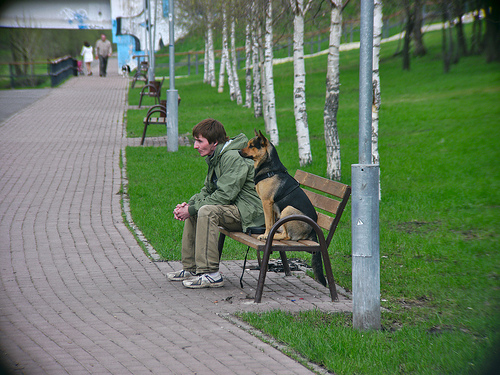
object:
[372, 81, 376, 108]
bark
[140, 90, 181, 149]
bench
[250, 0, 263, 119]
tree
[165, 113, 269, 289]
man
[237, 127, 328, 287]
dog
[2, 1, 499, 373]
park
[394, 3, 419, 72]
trees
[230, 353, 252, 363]
brick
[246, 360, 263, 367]
brick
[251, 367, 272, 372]
brick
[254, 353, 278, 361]
brick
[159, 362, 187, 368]
brick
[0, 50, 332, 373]
sidewalk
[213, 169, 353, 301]
bench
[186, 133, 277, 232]
coat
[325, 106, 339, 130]
bark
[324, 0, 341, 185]
tree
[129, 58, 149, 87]
bench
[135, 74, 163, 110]
bench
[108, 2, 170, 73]
building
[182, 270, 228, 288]
sneakers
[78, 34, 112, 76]
two people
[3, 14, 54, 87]
tree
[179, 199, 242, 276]
pants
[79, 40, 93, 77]
person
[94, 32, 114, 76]
person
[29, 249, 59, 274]
brick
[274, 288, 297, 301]
brick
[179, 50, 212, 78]
tree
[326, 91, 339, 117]
bark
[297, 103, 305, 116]
bark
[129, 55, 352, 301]
row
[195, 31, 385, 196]
row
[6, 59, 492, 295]
picture